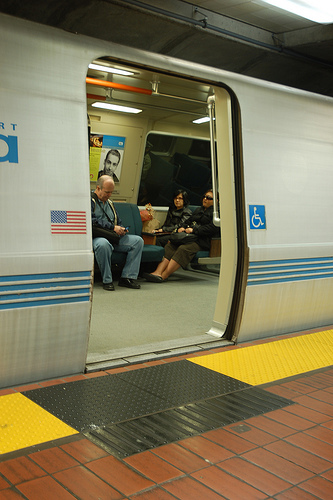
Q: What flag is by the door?
A: American flag.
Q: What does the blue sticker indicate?
A: Handicap.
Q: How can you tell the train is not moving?
A: The door is open.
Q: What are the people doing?
A: Sitting down.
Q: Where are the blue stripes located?
A: Side of the train.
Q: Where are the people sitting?
A: Inside the train.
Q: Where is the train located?
A: Underground.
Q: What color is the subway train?
A: White.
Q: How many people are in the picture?
A: Three.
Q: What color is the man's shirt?
A: Blue.